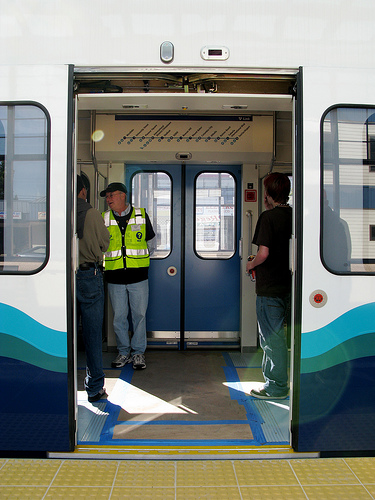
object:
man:
[98, 178, 157, 368]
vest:
[101, 208, 151, 272]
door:
[123, 161, 182, 348]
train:
[0, 1, 375, 457]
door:
[181, 161, 242, 346]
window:
[130, 169, 173, 260]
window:
[194, 170, 239, 261]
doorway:
[70, 65, 293, 451]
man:
[246, 172, 292, 401]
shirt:
[251, 205, 292, 298]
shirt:
[101, 211, 156, 285]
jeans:
[107, 280, 149, 355]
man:
[74, 172, 110, 403]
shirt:
[76, 198, 110, 266]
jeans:
[76, 269, 107, 393]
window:
[0, 97, 49, 277]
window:
[319, 102, 374, 275]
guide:
[117, 122, 250, 151]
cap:
[99, 182, 127, 197]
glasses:
[104, 193, 121, 200]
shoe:
[130, 351, 148, 371]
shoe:
[111, 348, 132, 369]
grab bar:
[94, 169, 100, 210]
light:
[159, 41, 175, 64]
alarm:
[244, 189, 257, 202]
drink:
[246, 254, 258, 282]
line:
[116, 419, 249, 425]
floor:
[82, 348, 293, 445]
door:
[296, 67, 375, 457]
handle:
[308, 288, 329, 308]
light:
[102, 375, 198, 416]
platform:
[2, 460, 375, 499]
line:
[104, 248, 149, 259]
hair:
[263, 169, 291, 205]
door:
[0, 65, 77, 452]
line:
[220, 348, 265, 441]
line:
[78, 438, 290, 447]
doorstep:
[76, 442, 294, 453]